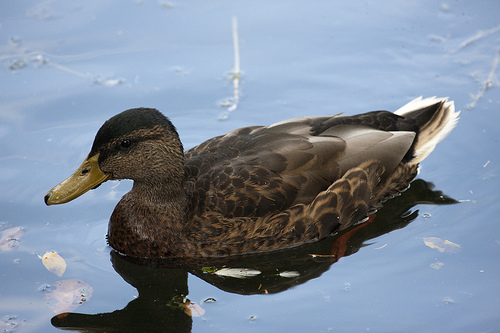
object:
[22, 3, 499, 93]
lake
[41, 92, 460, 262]
duck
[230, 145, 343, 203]
feather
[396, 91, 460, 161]
tail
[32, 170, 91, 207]
peck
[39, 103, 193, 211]
head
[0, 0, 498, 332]
water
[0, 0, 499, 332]
blue water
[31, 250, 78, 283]
leaves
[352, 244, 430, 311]
ripples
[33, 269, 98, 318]
leaves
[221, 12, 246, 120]
branch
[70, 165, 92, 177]
airway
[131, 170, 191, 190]
neck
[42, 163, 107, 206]
beak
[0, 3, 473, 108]
ripples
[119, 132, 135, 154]
eye